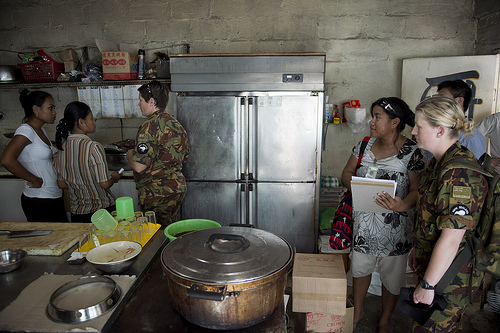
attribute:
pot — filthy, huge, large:
[162, 230, 293, 330]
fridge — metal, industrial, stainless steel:
[168, 54, 318, 255]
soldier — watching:
[410, 98, 498, 331]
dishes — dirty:
[85, 239, 143, 268]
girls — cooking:
[3, 89, 122, 218]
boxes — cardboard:
[292, 252, 355, 332]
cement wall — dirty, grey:
[0, 2, 499, 183]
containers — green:
[91, 194, 135, 231]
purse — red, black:
[328, 188, 353, 253]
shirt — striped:
[55, 132, 115, 211]